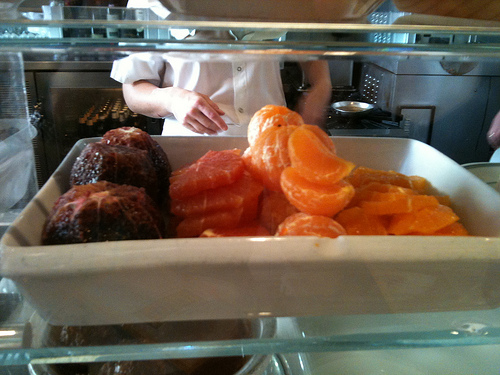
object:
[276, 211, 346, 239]
wedge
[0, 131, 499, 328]
pan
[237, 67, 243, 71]
button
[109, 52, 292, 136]
shirt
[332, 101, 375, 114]
frying pan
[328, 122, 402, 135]
stove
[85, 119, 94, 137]
bottle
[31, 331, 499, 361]
shelf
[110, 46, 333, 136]
person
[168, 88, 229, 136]
hand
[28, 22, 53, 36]
bag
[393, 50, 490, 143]
appliance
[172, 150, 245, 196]
grapefruit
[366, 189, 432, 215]
orange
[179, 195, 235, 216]
slice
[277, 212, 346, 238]
slice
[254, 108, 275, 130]
slice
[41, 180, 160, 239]
fruit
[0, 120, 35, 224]
tub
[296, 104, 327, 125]
hand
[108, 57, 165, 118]
arm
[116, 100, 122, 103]
bottle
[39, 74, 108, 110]
fridge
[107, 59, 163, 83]
sleeve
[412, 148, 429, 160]
light